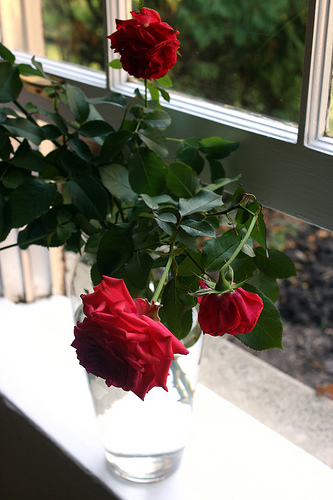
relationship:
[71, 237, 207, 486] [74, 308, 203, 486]
vase filled with water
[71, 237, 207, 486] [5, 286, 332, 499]
vase on top of window sill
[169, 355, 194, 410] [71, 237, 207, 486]
rose stem inside vase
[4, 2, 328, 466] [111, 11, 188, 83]
window next to rose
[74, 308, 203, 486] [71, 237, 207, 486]
water inside vase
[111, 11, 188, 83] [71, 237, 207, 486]
rose inside vase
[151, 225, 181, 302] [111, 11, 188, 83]
stem below rose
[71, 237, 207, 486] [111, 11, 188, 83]
vase has rose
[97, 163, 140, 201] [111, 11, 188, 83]
rose leaf next to rose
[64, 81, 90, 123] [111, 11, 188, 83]
rose leaf next to rose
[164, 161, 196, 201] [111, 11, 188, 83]
rose leaf next to rose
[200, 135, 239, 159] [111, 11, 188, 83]
rose leaf next to rose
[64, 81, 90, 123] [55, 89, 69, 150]
rose leaf has stem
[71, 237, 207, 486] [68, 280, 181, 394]
vase has rose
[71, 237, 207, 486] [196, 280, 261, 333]
vase has rose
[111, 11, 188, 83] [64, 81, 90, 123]
rose has rose leaf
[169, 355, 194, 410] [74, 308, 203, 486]
rose stem inside water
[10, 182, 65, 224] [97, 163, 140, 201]
rose leaf next to rose leaf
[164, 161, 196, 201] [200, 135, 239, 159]
rose leaf next to rose leaf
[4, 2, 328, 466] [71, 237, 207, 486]
window behind vase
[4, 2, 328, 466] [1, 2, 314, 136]
window has glass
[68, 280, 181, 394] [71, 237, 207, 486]
rose inside vase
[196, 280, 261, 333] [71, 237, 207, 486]
rose inside vase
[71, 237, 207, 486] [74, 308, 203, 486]
vase has water